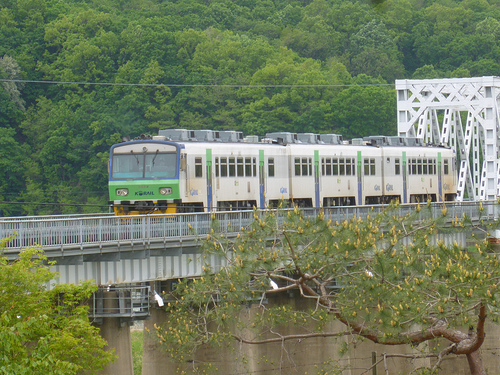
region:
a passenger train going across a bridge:
[91, 105, 489, 226]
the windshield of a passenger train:
[109, 153, 173, 182]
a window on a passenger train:
[191, 155, 201, 176]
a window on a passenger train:
[221, 155, 227, 178]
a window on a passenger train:
[229, 155, 236, 176]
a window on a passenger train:
[266, 158, 274, 179]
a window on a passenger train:
[293, 157, 300, 176]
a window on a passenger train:
[364, 157, 370, 174]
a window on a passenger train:
[393, 155, 400, 175]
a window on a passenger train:
[442, 157, 448, 174]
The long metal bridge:
[1, 204, 491, 256]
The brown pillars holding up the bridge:
[91, 285, 493, 372]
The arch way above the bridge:
[391, 75, 499, 197]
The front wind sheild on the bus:
[111, 154, 174, 181]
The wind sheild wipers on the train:
[130, 150, 159, 170]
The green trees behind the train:
[1, 69, 383, 132]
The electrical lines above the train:
[7, 71, 389, 88]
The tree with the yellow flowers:
[143, 203, 493, 363]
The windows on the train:
[185, 156, 450, 175]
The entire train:
[103, 141, 458, 212]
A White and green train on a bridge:
[107, 131, 457, 214]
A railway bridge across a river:
[2, 198, 499, 292]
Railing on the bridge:
[2, 201, 498, 247]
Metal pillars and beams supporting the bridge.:
[395, 76, 498, 199]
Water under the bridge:
[87, 285, 499, 372]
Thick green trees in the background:
[2, 0, 498, 213]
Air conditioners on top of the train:
[158, 130, 423, 144]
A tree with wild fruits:
[155, 208, 498, 374]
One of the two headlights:
[115, 185, 127, 197]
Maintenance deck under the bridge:
[92, 285, 149, 315]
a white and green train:
[106, 115, 486, 240]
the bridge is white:
[370, 58, 497, 192]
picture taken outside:
[13, 9, 480, 371]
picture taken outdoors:
[17, 15, 497, 356]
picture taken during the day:
[15, 13, 493, 369]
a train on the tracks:
[91, 95, 498, 285]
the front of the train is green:
[114, 178, 176, 200]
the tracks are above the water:
[64, 178, 496, 319]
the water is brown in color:
[128, 338, 179, 361]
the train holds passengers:
[191, 150, 451, 197]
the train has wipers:
[116, 154, 161, 167]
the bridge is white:
[394, 68, 494, 148]